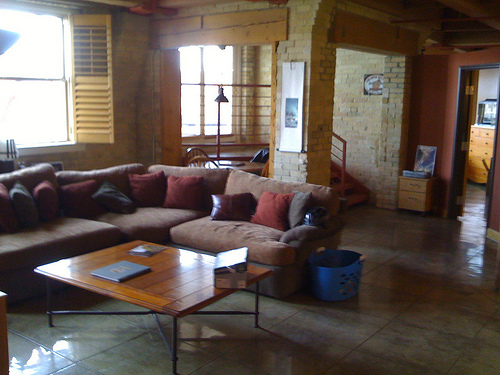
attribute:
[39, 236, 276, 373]
table — round shaped, wooden, square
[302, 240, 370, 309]
pail — blue, plastic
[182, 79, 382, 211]
starcase — metal, going up, small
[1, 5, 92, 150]
window — shining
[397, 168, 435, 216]
dresser — wooden, small, brown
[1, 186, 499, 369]
floor — shiny, brown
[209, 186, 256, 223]
pillow — brown, leather, red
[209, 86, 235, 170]
lamp — black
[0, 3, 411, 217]
wall — brick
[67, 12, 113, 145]
shudder — yellow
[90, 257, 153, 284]
book — blue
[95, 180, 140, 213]
pillow — black